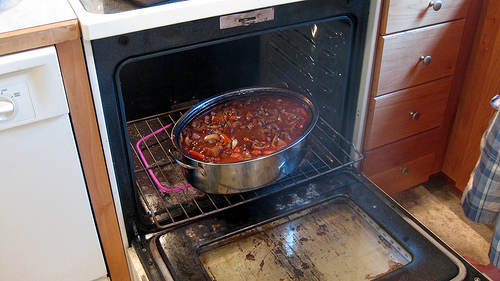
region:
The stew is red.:
[184, 101, 309, 150]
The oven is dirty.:
[185, 216, 385, 272]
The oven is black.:
[152, 31, 297, 81]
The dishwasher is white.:
[6, 141, 66, 233]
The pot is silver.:
[172, 82, 319, 191]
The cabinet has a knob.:
[419, 52, 435, 71]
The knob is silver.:
[416, 52, 438, 69]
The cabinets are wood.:
[379, 98, 439, 178]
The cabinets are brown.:
[382, 81, 435, 186]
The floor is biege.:
[425, 191, 457, 226]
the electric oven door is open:
[74, 1, 482, 278]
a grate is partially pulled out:
[128, 85, 361, 227]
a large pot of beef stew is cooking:
[165, 80, 319, 189]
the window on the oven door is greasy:
[190, 191, 412, 279]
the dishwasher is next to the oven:
[2, 47, 119, 279]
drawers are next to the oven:
[373, 1, 463, 193]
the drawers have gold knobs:
[393, 0, 440, 180]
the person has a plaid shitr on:
[455, 85, 499, 274]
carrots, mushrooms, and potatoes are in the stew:
[196, 113, 285, 155]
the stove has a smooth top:
[52, 0, 279, 18]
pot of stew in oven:
[161, 80, 324, 179]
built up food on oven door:
[232, 231, 330, 279]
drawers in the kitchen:
[366, 0, 464, 192]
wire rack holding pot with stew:
[126, 80, 364, 236]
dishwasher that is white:
[0, 53, 93, 279]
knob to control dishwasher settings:
[0, 83, 16, 126]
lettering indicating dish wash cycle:
[10, 85, 22, 100]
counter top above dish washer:
[1, 3, 69, 23]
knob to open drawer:
[415, 50, 436, 70]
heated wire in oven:
[136, 140, 174, 194]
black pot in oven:
[156, 110, 344, 188]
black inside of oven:
[97, 39, 390, 278]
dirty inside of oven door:
[209, 211, 388, 260]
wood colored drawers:
[393, 17, 454, 191]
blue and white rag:
[467, 139, 497, 218]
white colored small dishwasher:
[4, 84, 84, 263]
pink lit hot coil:
[133, 108, 181, 211]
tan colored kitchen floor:
[433, 204, 497, 251]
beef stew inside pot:
[221, 104, 292, 160]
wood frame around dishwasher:
[54, 37, 92, 166]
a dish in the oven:
[172, 77, 324, 193]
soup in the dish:
[177, 95, 301, 159]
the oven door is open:
[190, 196, 408, 271]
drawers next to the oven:
[361, 1, 471, 201]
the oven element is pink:
[134, 122, 191, 201]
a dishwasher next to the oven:
[1, 31, 113, 278]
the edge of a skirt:
[455, 79, 495, 271]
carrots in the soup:
[183, 94, 301, 166]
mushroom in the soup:
[177, 83, 297, 158]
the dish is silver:
[165, 78, 324, 198]